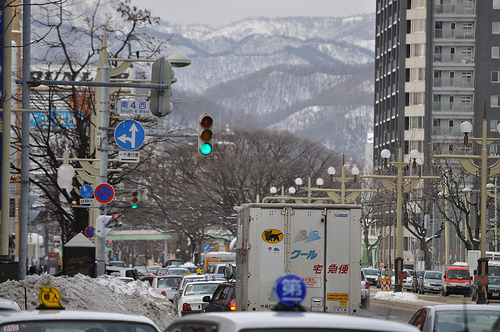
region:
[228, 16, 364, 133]
Snow capped mountains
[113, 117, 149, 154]
Two white arrows on blue sign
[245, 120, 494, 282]
A row of street lights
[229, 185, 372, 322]
Back of a white truck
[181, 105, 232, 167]
A traffic light lit up green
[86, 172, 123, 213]
A red and blue sign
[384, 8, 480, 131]
Windows on a building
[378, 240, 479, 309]
Vehicles in the street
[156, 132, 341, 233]
A tree bare of leaves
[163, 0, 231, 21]
Sky is gray and overcast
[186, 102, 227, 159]
the traffic light is hanging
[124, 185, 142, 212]
the traffic light is hanging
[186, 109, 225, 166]
the traffic light is green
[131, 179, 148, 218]
the traffic light is green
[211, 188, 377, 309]
the truck with japanese characters on it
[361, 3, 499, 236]
the tall building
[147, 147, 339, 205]
trees without leaves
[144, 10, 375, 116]
the snow covered mountains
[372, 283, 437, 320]
the snow in the street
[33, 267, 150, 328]
a pile of dirty snow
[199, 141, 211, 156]
Light is green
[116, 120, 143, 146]
Arrows on sign are white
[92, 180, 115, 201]
Circular blue and red traffic sign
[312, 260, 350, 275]
Red Chinese writing on truck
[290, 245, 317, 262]
Blue Chinese writing on truck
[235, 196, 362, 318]
Truck is large and white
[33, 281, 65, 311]
Yellow sign on top of car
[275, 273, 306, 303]
Blue sign on top of car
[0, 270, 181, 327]
Mound of snow next to white car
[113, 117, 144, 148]
Blue and white circular traffic sign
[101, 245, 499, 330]
Busy road way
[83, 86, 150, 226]
Road signs in chinese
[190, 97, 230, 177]
Stop light on green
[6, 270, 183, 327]
Dirty snow piled on the side of the road way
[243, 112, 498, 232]
Lamp poles lined down the middle of the road way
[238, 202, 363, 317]
Van with chinese writing on the back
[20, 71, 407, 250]
Big trees in the distance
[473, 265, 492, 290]
Red and green road sign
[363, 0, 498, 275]
Tall building stretching into the sky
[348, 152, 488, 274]
Bare trees lining the middle of the road way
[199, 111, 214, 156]
an electric traffic signal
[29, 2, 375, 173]
a mountain range in distance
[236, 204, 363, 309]
a white commercial truck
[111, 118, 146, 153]
a blue traffic sign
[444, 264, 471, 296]
a parked red van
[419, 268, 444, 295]
a parked silver car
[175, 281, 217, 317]
a white vehicle in street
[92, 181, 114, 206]
a red and blue street sign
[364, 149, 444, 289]
an overhead street light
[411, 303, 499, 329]
a silver car in street